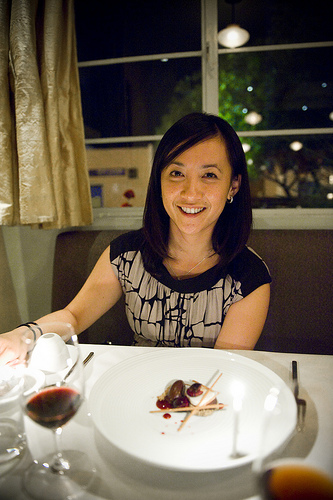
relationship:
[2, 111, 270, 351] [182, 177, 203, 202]
woman has a nose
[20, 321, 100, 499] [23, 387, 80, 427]
glass has wine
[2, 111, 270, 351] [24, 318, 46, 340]
woman has a bracelet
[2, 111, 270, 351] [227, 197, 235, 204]
woman has an earring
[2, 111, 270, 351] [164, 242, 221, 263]
woman has a necklace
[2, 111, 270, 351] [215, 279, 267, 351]
woman has an arm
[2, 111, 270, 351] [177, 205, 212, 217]
woman has a smile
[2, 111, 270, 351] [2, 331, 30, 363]
woman has a hand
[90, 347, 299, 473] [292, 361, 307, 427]
plate beside fork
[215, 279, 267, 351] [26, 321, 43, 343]
arm has a band